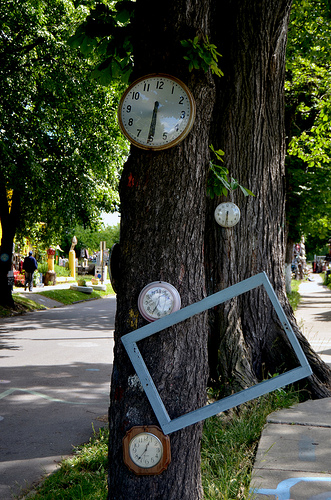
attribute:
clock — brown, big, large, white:
[114, 69, 198, 153]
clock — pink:
[135, 275, 184, 327]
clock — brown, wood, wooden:
[119, 421, 174, 479]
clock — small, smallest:
[212, 199, 244, 229]